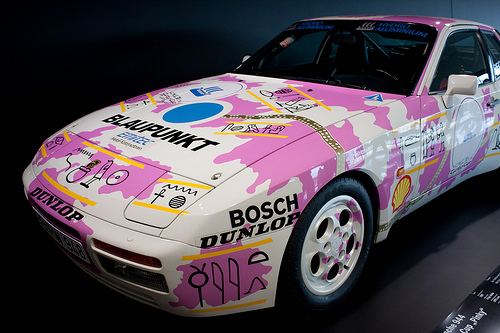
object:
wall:
[0, 1, 500, 72]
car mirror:
[241, 55, 251, 63]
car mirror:
[442, 74, 477, 108]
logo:
[391, 174, 414, 213]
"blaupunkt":
[102, 113, 221, 152]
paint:
[213, 119, 365, 230]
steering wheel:
[373, 68, 403, 87]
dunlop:
[200, 211, 301, 248]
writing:
[374, 23, 428, 38]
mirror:
[415, 73, 499, 105]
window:
[429, 31, 491, 93]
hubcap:
[301, 194, 365, 295]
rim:
[310, 251, 328, 277]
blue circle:
[161, 102, 224, 123]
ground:
[462, 171, 499, 214]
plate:
[31, 205, 93, 265]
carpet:
[324, 172, 500, 333]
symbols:
[65, 147, 130, 189]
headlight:
[96, 254, 169, 293]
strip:
[428, 266, 500, 333]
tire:
[286, 177, 374, 311]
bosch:
[229, 193, 299, 228]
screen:
[242, 20, 439, 95]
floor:
[0, 170, 500, 332]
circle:
[154, 100, 233, 127]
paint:
[150, 100, 183, 114]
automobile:
[22, 14, 500, 317]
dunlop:
[29, 186, 84, 221]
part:
[432, 235, 461, 255]